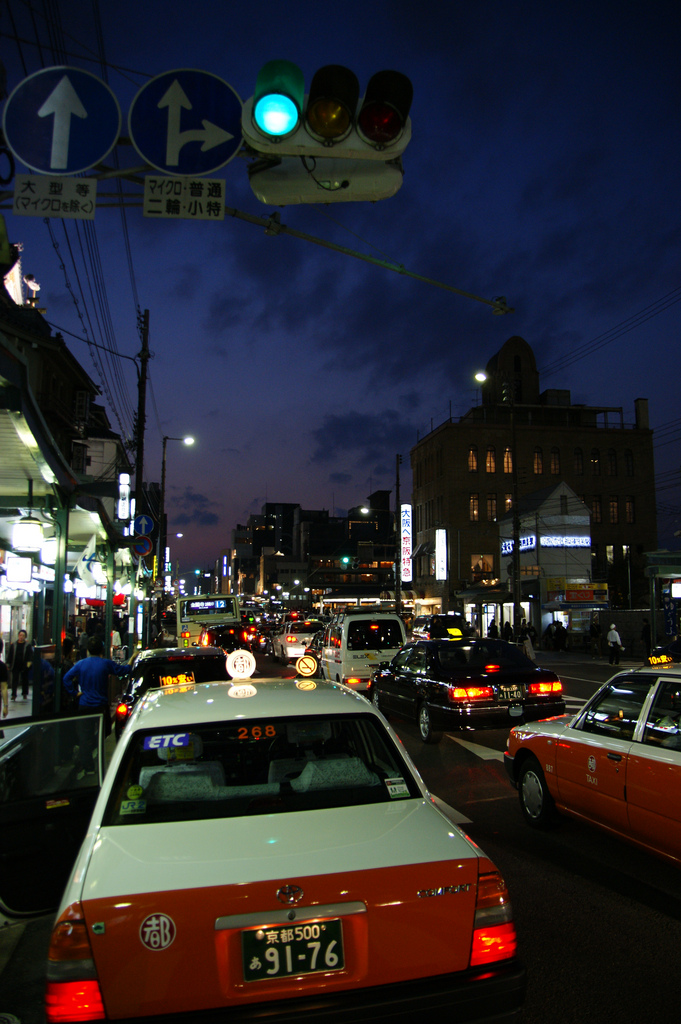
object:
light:
[254, 93, 299, 136]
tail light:
[470, 922, 518, 966]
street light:
[185, 438, 195, 446]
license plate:
[241, 918, 346, 984]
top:
[63, 655, 132, 707]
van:
[321, 605, 407, 690]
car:
[0, 649, 528, 1024]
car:
[504, 670, 681, 864]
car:
[366, 627, 566, 744]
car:
[321, 613, 408, 692]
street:
[0, 594, 681, 1024]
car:
[271, 619, 323, 665]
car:
[191, 622, 251, 654]